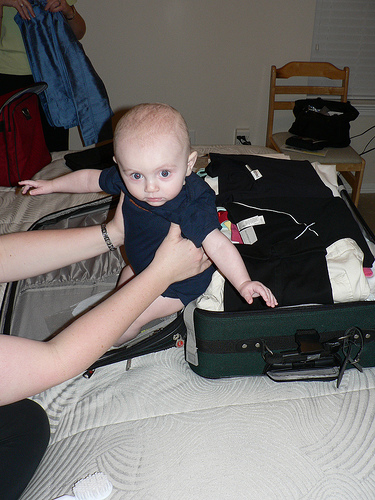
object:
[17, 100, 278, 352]
baby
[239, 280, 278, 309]
hand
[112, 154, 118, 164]
ear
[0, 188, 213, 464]
woman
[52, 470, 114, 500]
brush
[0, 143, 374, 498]
bed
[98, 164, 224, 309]
shirt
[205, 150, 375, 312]
clothes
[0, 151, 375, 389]
suitcase